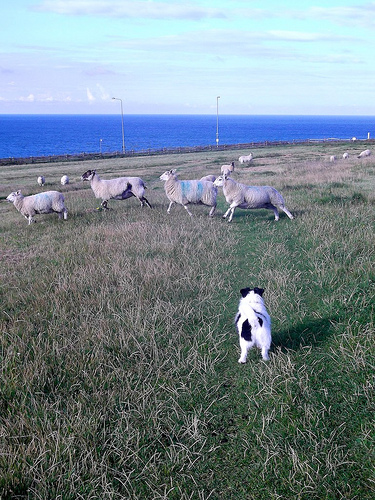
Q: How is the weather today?
A: It is cloudy.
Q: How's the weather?
A: It is cloudy.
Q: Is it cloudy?
A: Yes, it is cloudy.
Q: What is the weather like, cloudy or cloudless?
A: It is cloudy.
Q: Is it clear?
A: No, it is cloudy.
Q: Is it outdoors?
A: Yes, it is outdoors.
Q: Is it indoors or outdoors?
A: It is outdoors.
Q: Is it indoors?
A: No, it is outdoors.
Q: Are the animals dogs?
A: No, there are both sheep and dogs.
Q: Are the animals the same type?
A: No, there are both sheep and dogs.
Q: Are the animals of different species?
A: Yes, they are sheep and dogs.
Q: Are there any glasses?
A: No, there are no glasses.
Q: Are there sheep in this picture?
A: Yes, there is a sheep.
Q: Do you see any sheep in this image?
A: Yes, there is a sheep.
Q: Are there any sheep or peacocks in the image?
A: Yes, there is a sheep.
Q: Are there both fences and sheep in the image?
A: Yes, there are both a sheep and a fence.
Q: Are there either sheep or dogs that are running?
A: Yes, the sheep is running.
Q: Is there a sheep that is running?
A: Yes, there is a sheep that is running.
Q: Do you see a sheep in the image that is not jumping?
A: Yes, there is a sheep that is running .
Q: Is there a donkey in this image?
A: No, there are no donkeys.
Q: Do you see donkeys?
A: No, there are no donkeys.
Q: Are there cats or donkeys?
A: No, there are no donkeys or cats.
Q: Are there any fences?
A: Yes, there is a fence.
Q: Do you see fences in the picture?
A: Yes, there is a fence.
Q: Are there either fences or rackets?
A: Yes, there is a fence.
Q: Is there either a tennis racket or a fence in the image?
A: Yes, there is a fence.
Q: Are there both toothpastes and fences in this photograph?
A: No, there is a fence but no toothpastes.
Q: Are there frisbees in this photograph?
A: No, there are no frisbees.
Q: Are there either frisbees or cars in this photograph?
A: No, there are no frisbees or cars.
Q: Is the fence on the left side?
A: Yes, the fence is on the left of the image.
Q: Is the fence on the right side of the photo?
A: No, the fence is on the left of the image.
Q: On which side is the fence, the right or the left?
A: The fence is on the left of the image.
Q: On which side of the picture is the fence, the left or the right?
A: The fence is on the left of the image.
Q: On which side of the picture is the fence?
A: The fence is on the left of the image.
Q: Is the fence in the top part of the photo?
A: Yes, the fence is in the top of the image.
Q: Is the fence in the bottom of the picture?
A: No, the fence is in the top of the image.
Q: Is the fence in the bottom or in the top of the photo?
A: The fence is in the top of the image.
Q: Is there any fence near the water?
A: Yes, there is a fence near the water.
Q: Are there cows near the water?
A: No, there is a fence near the water.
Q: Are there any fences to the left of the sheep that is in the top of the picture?
A: Yes, there is a fence to the left of the sheep.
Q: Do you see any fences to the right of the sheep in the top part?
A: No, the fence is to the left of the sheep.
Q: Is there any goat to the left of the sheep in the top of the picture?
A: No, there is a fence to the left of the sheep.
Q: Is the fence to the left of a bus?
A: No, the fence is to the left of a sheep.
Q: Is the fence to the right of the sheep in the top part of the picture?
A: No, the fence is to the left of the sheep.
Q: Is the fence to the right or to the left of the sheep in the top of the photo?
A: The fence is to the left of the sheep.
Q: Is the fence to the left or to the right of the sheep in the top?
A: The fence is to the left of the sheep.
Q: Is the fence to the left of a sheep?
A: Yes, the fence is to the left of a sheep.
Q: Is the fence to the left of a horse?
A: No, the fence is to the left of a sheep.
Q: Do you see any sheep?
A: Yes, there is a sheep.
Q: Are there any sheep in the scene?
A: Yes, there is a sheep.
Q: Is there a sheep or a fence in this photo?
A: Yes, there is a sheep.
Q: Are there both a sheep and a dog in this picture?
A: Yes, there are both a sheep and a dog.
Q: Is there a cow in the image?
A: No, there are no cows.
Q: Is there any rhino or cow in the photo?
A: No, there are no cows or rhinos.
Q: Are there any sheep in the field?
A: Yes, there is a sheep in the field.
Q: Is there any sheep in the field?
A: Yes, there is a sheep in the field.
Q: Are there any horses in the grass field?
A: No, there is a sheep in the field.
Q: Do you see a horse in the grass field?
A: No, there is a sheep in the field.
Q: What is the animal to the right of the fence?
A: The animal is a sheep.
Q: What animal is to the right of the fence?
A: The animal is a sheep.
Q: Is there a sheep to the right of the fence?
A: Yes, there is a sheep to the right of the fence.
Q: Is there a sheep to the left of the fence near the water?
A: No, the sheep is to the right of the fence.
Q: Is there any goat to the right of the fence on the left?
A: No, there is a sheep to the right of the fence.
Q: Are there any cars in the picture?
A: No, there are no cars.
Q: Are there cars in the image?
A: No, there are no cars.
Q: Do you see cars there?
A: No, there are no cars.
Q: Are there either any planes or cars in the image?
A: No, there are no cars or planes.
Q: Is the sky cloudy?
A: Yes, the sky is cloudy.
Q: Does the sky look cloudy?
A: Yes, the sky is cloudy.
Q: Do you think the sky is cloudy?
A: Yes, the sky is cloudy.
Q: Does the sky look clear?
A: No, the sky is cloudy.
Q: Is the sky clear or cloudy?
A: The sky is cloudy.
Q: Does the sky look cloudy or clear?
A: The sky is cloudy.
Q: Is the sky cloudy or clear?
A: The sky is cloudy.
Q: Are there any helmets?
A: No, there are no helmets.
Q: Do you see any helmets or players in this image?
A: No, there are no helmets or players.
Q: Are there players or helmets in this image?
A: No, there are no helmets or players.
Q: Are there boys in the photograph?
A: No, there are no boys.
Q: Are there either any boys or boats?
A: No, there are no boys or boats.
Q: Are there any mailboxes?
A: No, there are no mailboxes.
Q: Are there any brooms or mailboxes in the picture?
A: No, there are no mailboxes or brooms.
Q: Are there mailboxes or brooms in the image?
A: No, there are no mailboxes or brooms.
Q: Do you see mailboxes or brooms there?
A: No, there are no mailboxes or brooms.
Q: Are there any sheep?
A: Yes, there is a sheep.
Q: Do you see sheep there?
A: Yes, there is a sheep.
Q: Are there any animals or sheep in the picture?
A: Yes, there is a sheep.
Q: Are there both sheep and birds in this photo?
A: No, there is a sheep but no birds.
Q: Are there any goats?
A: No, there are no goats.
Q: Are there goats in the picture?
A: No, there are no goats.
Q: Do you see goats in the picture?
A: No, there are no goats.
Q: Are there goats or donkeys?
A: No, there are no goats or donkeys.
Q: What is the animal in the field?
A: The animal is a sheep.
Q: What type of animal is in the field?
A: The animal is a sheep.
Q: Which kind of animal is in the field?
A: The animal is a sheep.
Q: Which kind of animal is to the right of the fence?
A: The animal is a sheep.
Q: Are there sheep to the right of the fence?
A: Yes, there is a sheep to the right of the fence.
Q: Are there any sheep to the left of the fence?
A: No, the sheep is to the right of the fence.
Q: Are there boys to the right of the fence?
A: No, there is a sheep to the right of the fence.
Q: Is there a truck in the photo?
A: No, there are no trucks.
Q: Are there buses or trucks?
A: No, there are no trucks or buses.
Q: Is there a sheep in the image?
A: Yes, there is a sheep.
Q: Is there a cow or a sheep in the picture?
A: Yes, there is a sheep.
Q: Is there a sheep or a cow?
A: Yes, there is a sheep.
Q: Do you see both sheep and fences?
A: Yes, there are both a sheep and a fence.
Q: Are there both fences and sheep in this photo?
A: Yes, there are both a sheep and a fence.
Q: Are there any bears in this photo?
A: No, there are no bears.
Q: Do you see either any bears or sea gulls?
A: No, there are no bears or sea gulls.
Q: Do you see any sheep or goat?
A: Yes, there is a sheep.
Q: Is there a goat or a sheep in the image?
A: Yes, there is a sheep.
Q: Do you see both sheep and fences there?
A: Yes, there are both a sheep and a fence.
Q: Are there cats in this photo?
A: No, there are no cats.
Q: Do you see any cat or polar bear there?
A: No, there are no cats or polar bears.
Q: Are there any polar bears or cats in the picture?
A: No, there are no cats or polar bears.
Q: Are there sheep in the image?
A: Yes, there is a sheep.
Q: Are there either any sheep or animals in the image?
A: Yes, there is a sheep.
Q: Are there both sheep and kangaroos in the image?
A: No, there is a sheep but no kangaroos.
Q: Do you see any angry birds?
A: No, there are no angry birds.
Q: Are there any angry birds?
A: No, there are no angry birds.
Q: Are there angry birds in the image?
A: No, there are no angry birds.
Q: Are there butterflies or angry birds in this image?
A: No, there are no angry birds or butterflies.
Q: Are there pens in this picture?
A: No, there are no pens.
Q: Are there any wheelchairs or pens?
A: No, there are no pens or wheelchairs.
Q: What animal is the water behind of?
A: The water is behind the sheep.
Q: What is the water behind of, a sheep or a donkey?
A: The water is behind a sheep.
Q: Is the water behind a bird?
A: No, the water is behind the sheep.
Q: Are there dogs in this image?
A: Yes, there is a dog.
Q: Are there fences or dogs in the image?
A: Yes, there is a dog.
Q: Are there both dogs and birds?
A: No, there is a dog but no birds.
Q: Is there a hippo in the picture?
A: No, there are no hippoes.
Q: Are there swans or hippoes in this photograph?
A: No, there are no hippoes or swans.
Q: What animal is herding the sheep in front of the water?
A: The dog is herding the sheep.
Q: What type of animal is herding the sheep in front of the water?
A: The animal is a dog.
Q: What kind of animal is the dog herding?
A: The dog is herding the sheep.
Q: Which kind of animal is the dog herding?
A: The dog is herding the sheep.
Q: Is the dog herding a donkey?
A: No, the dog is herding a sheep.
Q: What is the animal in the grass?
A: The animal is a dog.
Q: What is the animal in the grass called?
A: The animal is a dog.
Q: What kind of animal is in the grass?
A: The animal is a dog.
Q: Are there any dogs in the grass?
A: Yes, there is a dog in the grass.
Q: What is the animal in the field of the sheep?
A: The animal is a dog.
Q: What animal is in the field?
A: The animal is a dog.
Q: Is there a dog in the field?
A: Yes, there is a dog in the field.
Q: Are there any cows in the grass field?
A: No, there is a dog in the field.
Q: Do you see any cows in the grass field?
A: No, there is a dog in the field.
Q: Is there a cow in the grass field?
A: No, there is a dog in the field.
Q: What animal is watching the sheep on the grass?
A: The dog is watching the sheep.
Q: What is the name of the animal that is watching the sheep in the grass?
A: The animal is a dog.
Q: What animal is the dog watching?
A: The dog is watching the sheep.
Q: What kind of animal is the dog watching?
A: The dog is watching the sheep.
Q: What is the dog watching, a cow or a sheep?
A: The dog is watching a sheep.